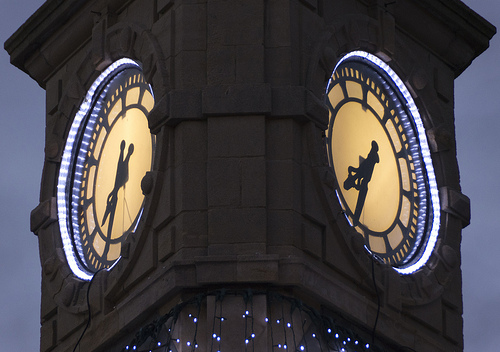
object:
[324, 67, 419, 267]
face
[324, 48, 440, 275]
clock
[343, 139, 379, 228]
hands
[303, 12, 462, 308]
frame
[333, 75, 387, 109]
marks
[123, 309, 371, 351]
lights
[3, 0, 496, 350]
tower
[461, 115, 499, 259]
sky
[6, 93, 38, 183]
clouds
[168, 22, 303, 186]
brick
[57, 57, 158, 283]
clocks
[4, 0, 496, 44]
top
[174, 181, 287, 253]
stone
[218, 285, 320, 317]
strings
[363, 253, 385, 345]
wire